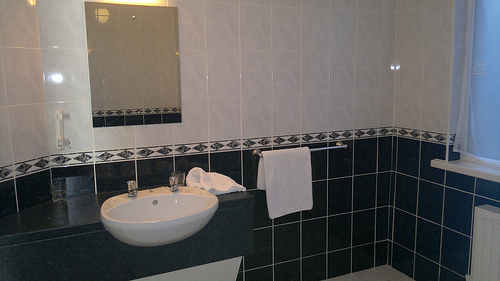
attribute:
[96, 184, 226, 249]
sink — white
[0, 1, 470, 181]
tile — white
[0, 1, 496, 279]
wall — marbled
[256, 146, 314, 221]
towel — white, folded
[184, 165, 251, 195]
towel — white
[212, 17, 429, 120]
wall — tiled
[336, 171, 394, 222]
tile — black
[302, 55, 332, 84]
tile — black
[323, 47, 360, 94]
tile — gray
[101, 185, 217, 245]
sink — porcelain, white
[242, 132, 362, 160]
rack — metal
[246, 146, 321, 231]
towel — white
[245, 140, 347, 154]
rail — chrome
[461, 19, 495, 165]
curtain — white, sheer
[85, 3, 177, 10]
light — glowing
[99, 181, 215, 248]
sink — white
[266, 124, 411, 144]
shapes — black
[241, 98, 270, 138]
tile — white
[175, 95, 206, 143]
tile — white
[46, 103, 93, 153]
tile — white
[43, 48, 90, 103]
tile — white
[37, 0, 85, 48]
tile — white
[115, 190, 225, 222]
sink bowl — white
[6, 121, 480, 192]
border — tiled